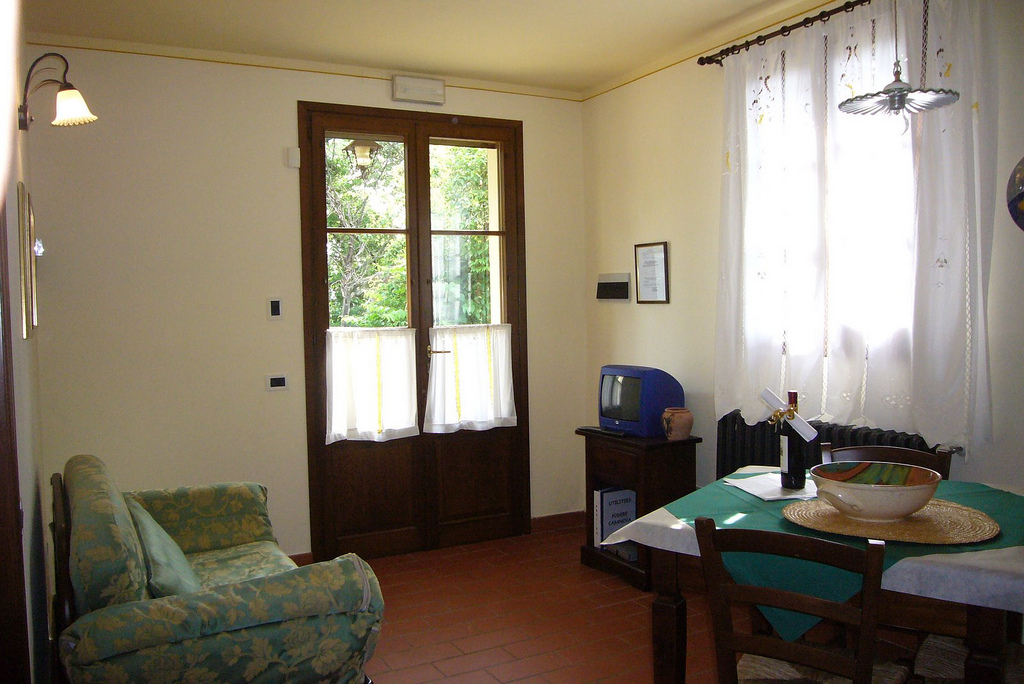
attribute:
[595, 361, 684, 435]
tv — small, blue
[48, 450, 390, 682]
couch — floral designed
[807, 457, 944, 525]
bowl — large, glass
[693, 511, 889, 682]
chair — dining chair, wooden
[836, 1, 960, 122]
light fixture — hanging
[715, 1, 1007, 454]
window curtain — white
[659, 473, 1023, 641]
table cloth — green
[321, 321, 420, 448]
curtain — small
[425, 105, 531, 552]
door — double, white